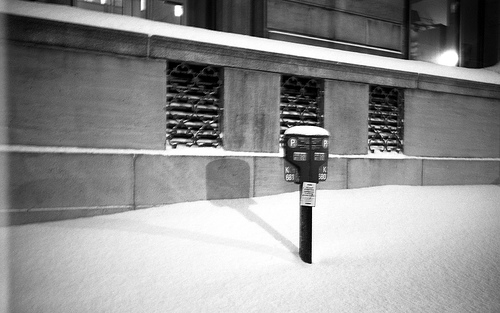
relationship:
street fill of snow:
[37, 219, 490, 310] [165, 211, 453, 266]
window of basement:
[158, 60, 241, 143] [86, 53, 495, 144]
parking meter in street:
[283, 125, 326, 233] [165, 211, 453, 266]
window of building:
[158, 60, 241, 143] [86, 53, 495, 144]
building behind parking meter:
[45, 8, 499, 160] [283, 125, 326, 233]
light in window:
[425, 36, 472, 70] [407, 9, 475, 80]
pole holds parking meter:
[298, 189, 317, 257] [283, 125, 326, 233]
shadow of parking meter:
[203, 161, 293, 248] [283, 125, 326, 233]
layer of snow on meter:
[281, 123, 332, 135] [292, 166, 324, 256]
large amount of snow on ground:
[37, 219, 490, 310] [125, 225, 493, 281]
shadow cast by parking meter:
[203, 161, 293, 248] [283, 125, 326, 233]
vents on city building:
[364, 83, 416, 164] [45, 8, 499, 160]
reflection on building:
[414, 46, 466, 62] [45, 8, 499, 160]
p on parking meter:
[284, 133, 301, 152] [283, 125, 326, 233]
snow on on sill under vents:
[167, 138, 415, 161] [154, 146, 411, 164]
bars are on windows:
[456, 6, 488, 85] [385, 4, 490, 83]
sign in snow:
[134, 6, 271, 34] [281, 123, 332, 135]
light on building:
[425, 36, 472, 70] [45, 8, 499, 160]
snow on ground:
[37, 219, 490, 310] [108, 218, 491, 297]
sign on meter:
[319, 165, 329, 182] [292, 166, 324, 256]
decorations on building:
[129, 4, 264, 34] [45, 8, 499, 160]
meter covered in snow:
[292, 166, 324, 256] [125, 225, 493, 281]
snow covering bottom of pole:
[255, 231, 377, 282] [298, 189, 317, 257]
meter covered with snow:
[292, 166, 324, 256] [255, 231, 377, 282]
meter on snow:
[292, 166, 324, 256] [281, 123, 332, 135]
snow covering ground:
[281, 123, 332, 135] [108, 218, 491, 297]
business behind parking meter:
[45, 8, 499, 160] [283, 125, 326, 233]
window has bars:
[158, 60, 241, 143] [166, 64, 225, 128]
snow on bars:
[168, 141, 223, 156] [166, 64, 225, 128]